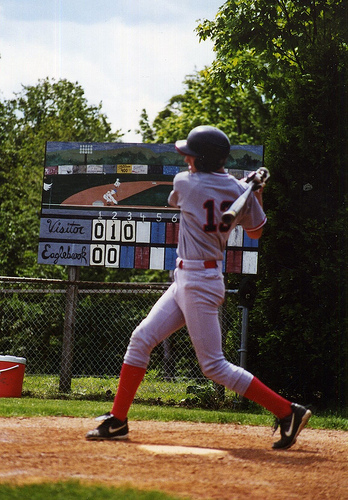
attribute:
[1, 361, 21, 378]
handle — white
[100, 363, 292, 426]
socks — orange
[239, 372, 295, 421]
sock — red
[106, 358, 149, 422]
sock — red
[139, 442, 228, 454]
plate — on ground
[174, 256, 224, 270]
belt — red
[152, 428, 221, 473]
plate — on shoe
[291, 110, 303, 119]
ground — on field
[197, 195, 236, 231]
number 13 — on head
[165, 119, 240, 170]
helmet — on head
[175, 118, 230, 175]
helmet — on head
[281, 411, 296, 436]
nike swoosh — on field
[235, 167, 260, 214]
bat — black 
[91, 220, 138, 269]
numbers — black 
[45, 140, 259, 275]
scoreboard — on field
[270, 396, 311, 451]
shoe — on foot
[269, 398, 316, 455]
shoe — black and white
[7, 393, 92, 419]
grass — on field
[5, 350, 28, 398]
cooler — on shoe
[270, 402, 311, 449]
baseball cleat — on shoe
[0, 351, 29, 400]
cooler — red, white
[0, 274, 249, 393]
fence — chain link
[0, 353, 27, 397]
cooler — red